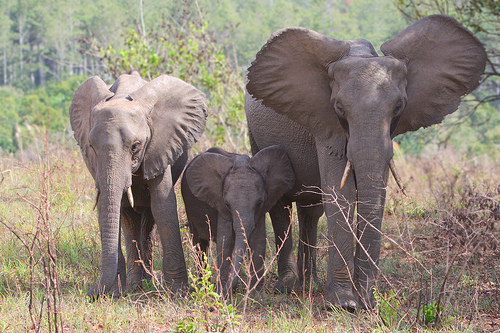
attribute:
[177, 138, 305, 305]
baby elephant — in middle, looking down, small, adorable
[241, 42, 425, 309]
elephant — huge, standing, gray, wrinkled, large, mommy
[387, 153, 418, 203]
tusk — white, dirty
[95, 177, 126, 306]
trunk — long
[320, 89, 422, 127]
eyes — black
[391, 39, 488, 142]
big ears — floppy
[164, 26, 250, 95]
bushes — green, dry, grouped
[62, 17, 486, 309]
elephants — family, 3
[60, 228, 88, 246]
grass — dry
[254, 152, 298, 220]
ear — small, flapping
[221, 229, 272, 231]
small tusks — white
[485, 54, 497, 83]
branch — bare